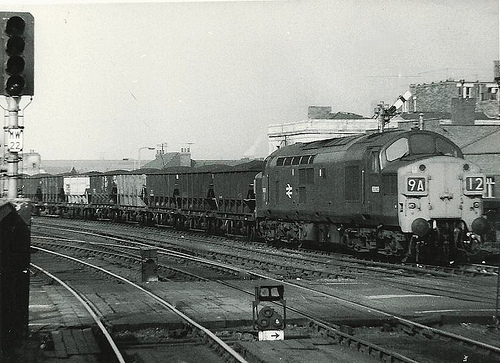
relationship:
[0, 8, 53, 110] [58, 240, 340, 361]
light near tracks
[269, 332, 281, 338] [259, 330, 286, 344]
arrow on sign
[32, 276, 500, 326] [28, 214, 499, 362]
road across track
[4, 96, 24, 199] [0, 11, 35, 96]
pole supporting light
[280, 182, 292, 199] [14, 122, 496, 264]
white logo on train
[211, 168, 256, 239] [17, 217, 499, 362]
train car on track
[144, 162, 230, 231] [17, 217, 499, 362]
train car on track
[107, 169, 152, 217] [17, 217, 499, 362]
train car on track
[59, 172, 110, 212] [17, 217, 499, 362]
train car on track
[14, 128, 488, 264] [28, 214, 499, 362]
train on track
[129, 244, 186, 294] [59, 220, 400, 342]
box on tracks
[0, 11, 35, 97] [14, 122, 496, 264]
light are for train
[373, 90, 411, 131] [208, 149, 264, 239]
shoot for loading coal in train car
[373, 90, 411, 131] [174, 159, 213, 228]
shoot for loading coal in train car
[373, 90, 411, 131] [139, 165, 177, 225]
shoot for loading coal in train car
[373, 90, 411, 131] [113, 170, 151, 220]
shoot for loading coal in train car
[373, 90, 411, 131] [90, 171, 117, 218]
shoot for loading coal in train car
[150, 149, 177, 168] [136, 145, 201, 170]
roof on building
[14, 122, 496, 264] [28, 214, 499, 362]
train on track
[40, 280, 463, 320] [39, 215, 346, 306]
road on tracks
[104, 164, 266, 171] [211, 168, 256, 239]
coal in train car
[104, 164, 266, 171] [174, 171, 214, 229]
coal in train car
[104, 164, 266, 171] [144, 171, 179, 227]
coal in train car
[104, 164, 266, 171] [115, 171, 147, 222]
coal in train car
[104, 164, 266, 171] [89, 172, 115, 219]
coal in train car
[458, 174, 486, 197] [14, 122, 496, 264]
number on train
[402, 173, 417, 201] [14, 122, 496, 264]
number on train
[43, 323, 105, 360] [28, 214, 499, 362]
wood planks beside track